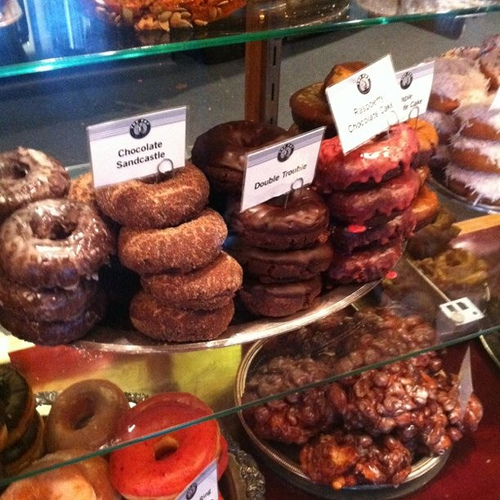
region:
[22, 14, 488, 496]
pastries on several shelves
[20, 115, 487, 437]
shelf for the pastries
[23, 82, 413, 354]
platter with pastries on them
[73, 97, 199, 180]
tag with pastry name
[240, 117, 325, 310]
stack of the pastries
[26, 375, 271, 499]
metal platter with pastries on it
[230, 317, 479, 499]
metal container with pastries in them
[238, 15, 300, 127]
supportive pole with racks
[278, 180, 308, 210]
clip holding tag in pastry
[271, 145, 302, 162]
brand logo and image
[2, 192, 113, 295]
FRESH GLAZED DELICIOUS DONUT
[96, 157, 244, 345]
STACK OF FRESH DONUTE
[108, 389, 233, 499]
FRESH RED GLAZED DONUT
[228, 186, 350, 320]
STACK OF GLAZED DONUTS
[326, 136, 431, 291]
STACK OF GLAZED DONUTS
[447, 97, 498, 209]
STACK OF ICED DONUTE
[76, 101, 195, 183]
SIGN FOR CHOCOLATE SANDCASTLE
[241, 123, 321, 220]
SIGN FOR DONUT STACK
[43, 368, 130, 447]
SMALL FRESH GLAZED DONUT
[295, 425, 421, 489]
FRESH BAKED DONUT IN TIN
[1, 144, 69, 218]
donut is next to donut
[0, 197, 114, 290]
donut is next to donut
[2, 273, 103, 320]
donut is next to donut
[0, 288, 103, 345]
donut is next to donut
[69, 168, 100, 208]
donut is next to donut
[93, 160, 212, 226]
donut is next to donut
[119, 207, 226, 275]
donut is next to donut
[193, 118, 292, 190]
donut is next to donut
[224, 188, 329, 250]
donut is next to donut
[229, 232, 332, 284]
donut is next to donut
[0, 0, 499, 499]
bakery case of pastries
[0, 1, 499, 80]
glass shelf on top of bakery case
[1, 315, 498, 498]
middle glass shelf of bakery case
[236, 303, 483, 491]
apple fritters on bottom shelf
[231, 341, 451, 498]
round metal object holding apple fritters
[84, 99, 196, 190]
sign for Chocolate Sandcastle pastries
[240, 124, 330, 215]
sign for Double Trouble pastries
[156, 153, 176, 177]
metal clip to keep sign in place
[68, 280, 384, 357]
metal plate holding variety of pastries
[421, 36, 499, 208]
pastries covered in white coconut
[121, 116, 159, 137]
black design on sign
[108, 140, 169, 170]
doughnut name on white sign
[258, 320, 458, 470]
pile of brown pastries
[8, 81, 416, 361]
row of doughnuts on platter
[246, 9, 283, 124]
brown metal shelf pole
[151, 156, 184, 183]
black metal clip holding sign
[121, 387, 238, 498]
stack of glazed doughnuts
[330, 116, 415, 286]
doughnuts covered in pink glaze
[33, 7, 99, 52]
light reflection on glass shelf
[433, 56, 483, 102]
shredded coconut on doughnut